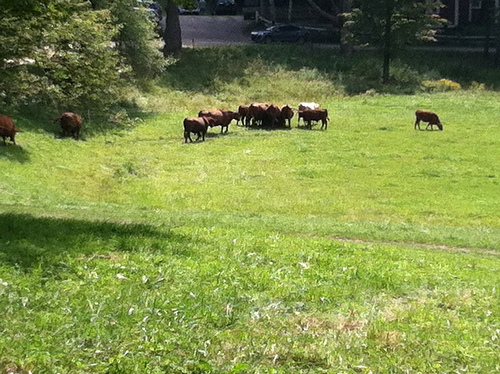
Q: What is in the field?
A: Cows.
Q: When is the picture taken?
A: Daytime.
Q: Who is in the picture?
A: Animals.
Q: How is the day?
A: Sunny.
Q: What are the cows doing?
A: Grazing.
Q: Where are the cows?
A: In the field.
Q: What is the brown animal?
A: A cow.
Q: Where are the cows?
A: At the field.